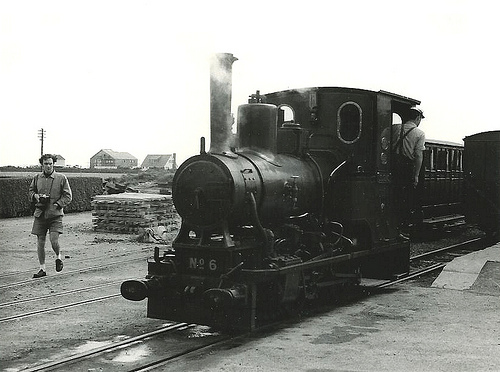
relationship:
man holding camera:
[22, 149, 81, 281] [34, 187, 51, 211]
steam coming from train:
[199, 45, 247, 145] [116, 49, 483, 321]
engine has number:
[129, 99, 489, 368] [189, 253, 225, 276]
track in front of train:
[55, 289, 173, 362] [15, 324, 225, 369]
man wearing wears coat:
[10, 128, 115, 314] [25, 171, 75, 220]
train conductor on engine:
[393, 105, 425, 234] [138, 48, 443, 343]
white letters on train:
[178, 251, 221, 272] [116, 49, 483, 321]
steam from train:
[199, 45, 247, 145] [144, 67, 498, 344]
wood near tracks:
[88, 189, 180, 240] [0, 238, 499, 370]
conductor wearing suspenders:
[393, 105, 425, 236] [391, 123, 417, 155]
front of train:
[116, 136, 261, 338] [116, 49, 483, 321]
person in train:
[388, 105, 424, 240] [116, 49, 483, 321]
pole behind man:
[11, 110, 83, 162] [15, 123, 92, 260]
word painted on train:
[186, 252, 221, 273] [116, 37, 499, 339]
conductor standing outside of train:
[393, 105, 425, 236] [138, 94, 496, 321]